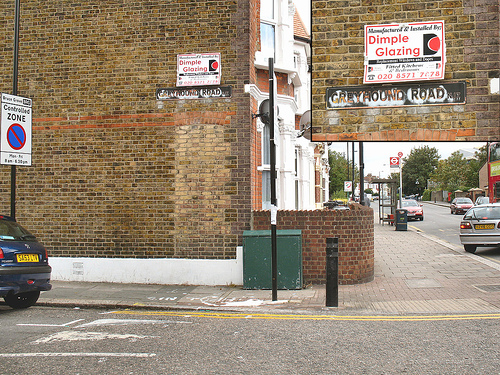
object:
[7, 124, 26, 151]
circle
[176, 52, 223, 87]
sign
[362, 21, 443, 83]
sign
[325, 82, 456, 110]
sign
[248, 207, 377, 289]
brick wall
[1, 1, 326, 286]
building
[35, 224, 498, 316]
sidewalk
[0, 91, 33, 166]
sign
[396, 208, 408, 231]
trashcan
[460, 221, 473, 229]
car lights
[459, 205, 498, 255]
car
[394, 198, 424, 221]
car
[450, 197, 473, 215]
car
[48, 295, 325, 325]
curb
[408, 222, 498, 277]
curb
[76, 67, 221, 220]
brick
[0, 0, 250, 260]
wall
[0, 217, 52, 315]
car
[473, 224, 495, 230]
license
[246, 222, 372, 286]
wall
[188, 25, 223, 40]
brick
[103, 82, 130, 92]
brick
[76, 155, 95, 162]
brick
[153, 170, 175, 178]
brick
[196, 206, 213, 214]
brick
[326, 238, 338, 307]
black post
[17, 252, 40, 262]
license plate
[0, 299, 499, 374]
grey street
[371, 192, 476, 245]
grey street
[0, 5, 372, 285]
brick building